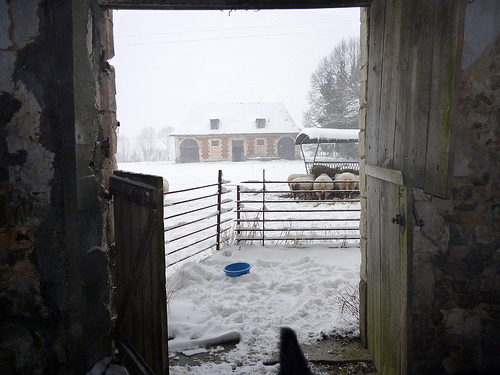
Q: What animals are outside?
A: Sheep.